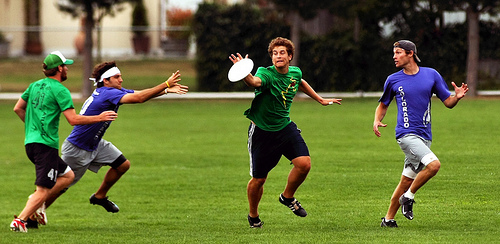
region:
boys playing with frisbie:
[0, 35, 477, 242]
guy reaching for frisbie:
[201, 27, 359, 187]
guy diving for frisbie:
[31, 45, 200, 224]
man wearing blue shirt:
[375, 24, 460, 194]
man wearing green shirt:
[233, 24, 326, 170]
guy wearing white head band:
[71, 60, 148, 106]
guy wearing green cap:
[18, 37, 93, 92]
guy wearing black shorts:
[243, 105, 325, 191]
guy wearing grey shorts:
[375, 121, 466, 185]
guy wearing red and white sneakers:
[0, 205, 59, 242]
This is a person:
[358, 25, 478, 237]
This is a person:
[211, 23, 348, 234]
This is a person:
[12, 32, 197, 242]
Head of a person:
[382, 28, 425, 79]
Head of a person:
[263, 29, 304, 81]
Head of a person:
[85, 42, 135, 102]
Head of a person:
[40, 37, 75, 89]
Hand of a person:
[431, 65, 478, 112]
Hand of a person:
[296, 69, 355, 111]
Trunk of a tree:
[461, 1, 483, 101]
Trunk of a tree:
[288, 5, 306, 90]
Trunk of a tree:
[75, 2, 102, 109]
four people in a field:
[1, 26, 471, 233]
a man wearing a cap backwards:
[388, 35, 430, 76]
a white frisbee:
[211, 49, 256, 93]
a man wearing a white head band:
[85, 39, 145, 95]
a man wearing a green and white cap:
[46, 32, 77, 98]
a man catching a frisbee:
[212, 27, 309, 124]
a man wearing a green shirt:
[242, 28, 302, 159]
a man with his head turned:
[351, 30, 431, 87]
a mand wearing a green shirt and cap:
[23, 40, 76, 185]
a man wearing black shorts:
[246, 48, 313, 190]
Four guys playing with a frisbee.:
[11, 36, 480, 227]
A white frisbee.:
[224, 55, 254, 82]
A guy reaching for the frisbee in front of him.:
[222, 36, 341, 223]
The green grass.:
[3, 59, 492, 242]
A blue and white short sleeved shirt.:
[379, 68, 446, 138]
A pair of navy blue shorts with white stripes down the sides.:
[246, 123, 311, 175]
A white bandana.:
[87, 67, 120, 85]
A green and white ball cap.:
[40, 50, 74, 69]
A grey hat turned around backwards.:
[394, 38, 423, 62]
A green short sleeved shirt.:
[22, 81, 70, 146]